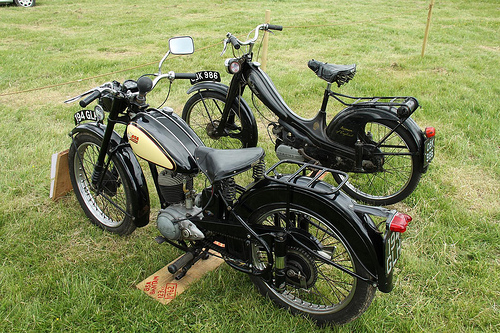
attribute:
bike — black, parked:
[64, 37, 412, 328]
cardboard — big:
[136, 239, 229, 306]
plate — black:
[380, 229, 400, 277]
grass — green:
[1, 1, 498, 332]